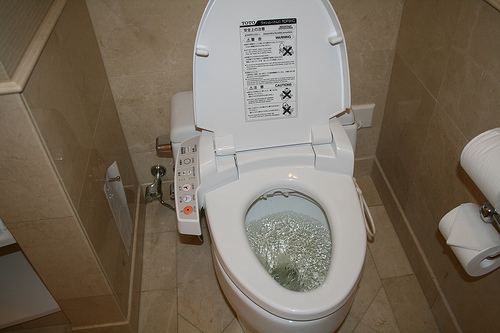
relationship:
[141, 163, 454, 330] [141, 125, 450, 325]
floor made of tiles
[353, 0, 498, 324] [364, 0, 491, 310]
wall made of tiles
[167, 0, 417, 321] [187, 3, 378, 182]
toilet has lid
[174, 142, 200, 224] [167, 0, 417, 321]
controls for toilet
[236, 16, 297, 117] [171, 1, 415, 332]
instructions for toilet use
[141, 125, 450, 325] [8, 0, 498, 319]
tiles on walls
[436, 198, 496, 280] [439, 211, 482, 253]
toilet paper has end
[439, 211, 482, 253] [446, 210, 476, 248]
end shaped into triangle